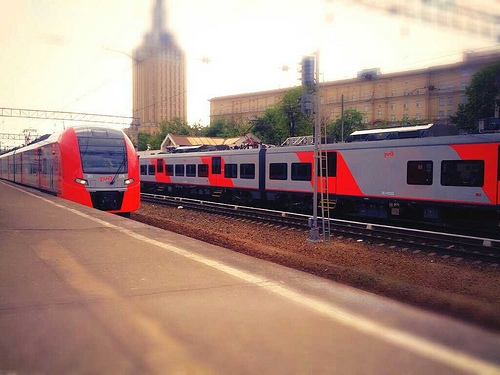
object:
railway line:
[140, 198, 499, 264]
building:
[208, 54, 500, 129]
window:
[406, 159, 433, 186]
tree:
[445, 59, 500, 134]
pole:
[308, 49, 320, 241]